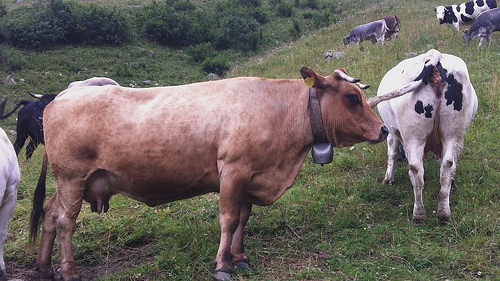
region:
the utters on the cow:
[72, 177, 109, 213]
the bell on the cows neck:
[307, 76, 332, 173]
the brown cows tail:
[22, 141, 59, 246]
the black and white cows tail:
[357, 48, 451, 135]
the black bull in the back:
[19, 79, 59, 151]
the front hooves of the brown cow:
[180, 242, 279, 276]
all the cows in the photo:
[3, 1, 488, 232]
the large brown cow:
[37, 75, 387, 240]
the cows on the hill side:
[339, 8, 499, 76]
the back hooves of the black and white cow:
[399, 151, 474, 231]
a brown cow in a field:
[41, 64, 388, 274]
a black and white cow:
[384, 48, 487, 228]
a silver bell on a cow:
[312, 131, 337, 178]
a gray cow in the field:
[339, 21, 389, 56]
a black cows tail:
[3, 97, 33, 120]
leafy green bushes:
[11, 9, 274, 56]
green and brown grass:
[269, 188, 400, 269]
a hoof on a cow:
[212, 268, 242, 278]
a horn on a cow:
[337, 66, 362, 82]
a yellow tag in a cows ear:
[305, 68, 317, 90]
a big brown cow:
[48, 53, 407, 255]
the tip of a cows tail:
[18, 144, 67, 249]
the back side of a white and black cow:
[384, 25, 486, 183]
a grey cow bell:
[307, 130, 340, 182]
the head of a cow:
[301, 56, 393, 186]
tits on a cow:
[78, 153, 169, 225]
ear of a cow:
[287, 53, 358, 94]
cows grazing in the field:
[320, 0, 418, 55]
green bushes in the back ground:
[27, 0, 227, 60]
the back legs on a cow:
[18, 163, 145, 270]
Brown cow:
[28, 68, 388, 277]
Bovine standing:
[25, 63, 390, 279]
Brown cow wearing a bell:
[28, 65, 390, 277]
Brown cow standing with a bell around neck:
[26, 65, 388, 279]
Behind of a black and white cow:
[389, 47, 481, 224]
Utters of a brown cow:
[81, 170, 120, 213]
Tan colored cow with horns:
[28, 64, 390, 279]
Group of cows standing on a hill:
[325, 0, 498, 46]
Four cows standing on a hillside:
[341, 0, 499, 50]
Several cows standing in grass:
[343, 0, 499, 47]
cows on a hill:
[208, 4, 482, 209]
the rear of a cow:
[416, 52, 475, 229]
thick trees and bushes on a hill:
[1, 10, 228, 112]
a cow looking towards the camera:
[425, 4, 484, 30]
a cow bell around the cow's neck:
[304, 66, 336, 178]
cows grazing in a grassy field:
[331, 3, 488, 75]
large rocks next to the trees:
[113, 32, 163, 83]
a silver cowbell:
[300, 72, 335, 160]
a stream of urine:
[101, 204, 121, 279]